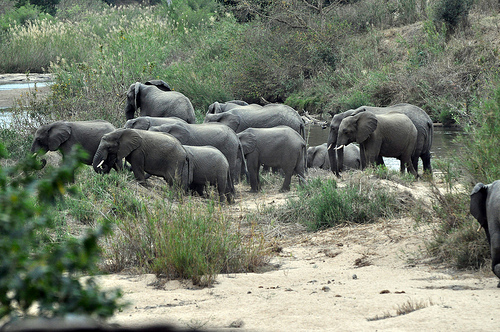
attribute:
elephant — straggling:
[334, 111, 421, 176]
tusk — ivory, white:
[334, 143, 343, 152]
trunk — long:
[336, 139, 346, 170]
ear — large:
[353, 110, 379, 145]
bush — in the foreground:
[1, 134, 124, 331]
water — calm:
[2, 107, 485, 174]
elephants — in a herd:
[16, 75, 442, 207]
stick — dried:
[270, 219, 299, 242]